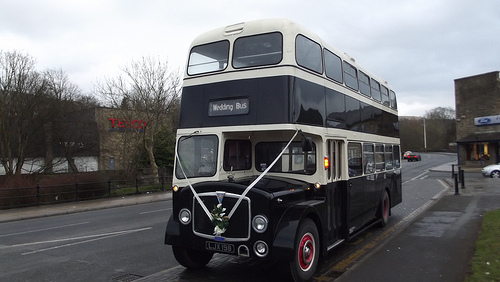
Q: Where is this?
A: This is at the road.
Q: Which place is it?
A: It is a road.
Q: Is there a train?
A: No, there are no trains.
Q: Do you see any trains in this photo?
A: No, there are no trains.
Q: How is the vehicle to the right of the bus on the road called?
A: The vehicle is a car.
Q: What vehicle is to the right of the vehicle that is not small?
A: The vehicle is a car.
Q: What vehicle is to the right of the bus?
A: The vehicle is a car.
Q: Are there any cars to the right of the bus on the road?
A: Yes, there is a car to the right of the bus.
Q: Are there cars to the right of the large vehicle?
A: Yes, there is a car to the right of the bus.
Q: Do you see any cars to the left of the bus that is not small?
A: No, the car is to the right of the bus.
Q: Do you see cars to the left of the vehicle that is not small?
A: No, the car is to the right of the bus.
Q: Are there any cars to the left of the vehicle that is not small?
A: No, the car is to the right of the bus.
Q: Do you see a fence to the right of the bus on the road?
A: No, there is a car to the right of the bus.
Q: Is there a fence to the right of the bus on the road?
A: No, there is a car to the right of the bus.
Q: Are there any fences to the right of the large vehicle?
A: No, there is a car to the right of the bus.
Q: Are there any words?
A: Yes, there are words.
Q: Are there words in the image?
A: Yes, there are words.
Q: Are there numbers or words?
A: Yes, there are words.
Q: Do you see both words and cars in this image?
A: Yes, there are both words and a car.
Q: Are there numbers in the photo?
A: No, there are no numbers.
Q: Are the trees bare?
A: Yes, the trees are bare.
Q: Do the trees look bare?
A: Yes, the trees are bare.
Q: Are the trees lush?
A: No, the trees are bare.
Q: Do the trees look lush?
A: No, the trees are bare.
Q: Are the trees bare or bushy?
A: The trees are bare.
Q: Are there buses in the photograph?
A: Yes, there is a bus.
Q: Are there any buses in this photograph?
A: Yes, there is a bus.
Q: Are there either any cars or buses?
A: Yes, there is a bus.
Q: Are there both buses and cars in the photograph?
A: Yes, there are both a bus and a car.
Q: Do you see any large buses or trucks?
A: Yes, there is a large bus.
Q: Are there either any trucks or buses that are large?
A: Yes, the bus is large.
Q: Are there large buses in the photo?
A: Yes, there is a large bus.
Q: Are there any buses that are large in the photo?
A: Yes, there is a large bus.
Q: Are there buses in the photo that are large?
A: Yes, there is a bus that is large.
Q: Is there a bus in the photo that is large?
A: Yes, there is a bus that is large.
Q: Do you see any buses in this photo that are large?
A: Yes, there is a bus that is large.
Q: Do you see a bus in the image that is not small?
A: Yes, there is a large bus.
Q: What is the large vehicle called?
A: The vehicle is a bus.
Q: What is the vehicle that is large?
A: The vehicle is a bus.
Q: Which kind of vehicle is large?
A: The vehicle is a bus.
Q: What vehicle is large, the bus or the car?
A: The bus is large.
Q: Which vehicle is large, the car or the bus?
A: The bus is large.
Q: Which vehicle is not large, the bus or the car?
A: The car is not large.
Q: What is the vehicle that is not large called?
A: The vehicle is a car.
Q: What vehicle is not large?
A: The vehicle is a car.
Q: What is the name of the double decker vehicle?
A: The vehicle is a bus.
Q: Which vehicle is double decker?
A: The vehicle is a bus.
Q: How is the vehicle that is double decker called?
A: The vehicle is a bus.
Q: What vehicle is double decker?
A: The vehicle is a bus.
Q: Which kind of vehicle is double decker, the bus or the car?
A: The bus is double decker.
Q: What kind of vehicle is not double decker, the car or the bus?
A: The car is not double decker.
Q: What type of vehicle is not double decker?
A: The vehicle is a car.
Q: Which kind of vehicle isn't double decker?
A: The vehicle is a car.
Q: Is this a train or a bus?
A: This is a bus.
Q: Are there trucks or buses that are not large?
A: No, there is a bus but it is large.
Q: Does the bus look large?
A: Yes, the bus is large.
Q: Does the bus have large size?
A: Yes, the bus is large.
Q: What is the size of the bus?
A: The bus is large.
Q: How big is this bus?
A: The bus is large.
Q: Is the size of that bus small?
A: No, the bus is large.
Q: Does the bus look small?
A: No, the bus is large.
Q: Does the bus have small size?
A: No, the bus is large.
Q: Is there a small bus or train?
A: No, there is a bus but it is large.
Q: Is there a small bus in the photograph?
A: No, there is a bus but it is large.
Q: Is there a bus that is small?
A: No, there is a bus but it is large.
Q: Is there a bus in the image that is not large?
A: No, there is a bus but it is large.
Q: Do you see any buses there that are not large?
A: No, there is a bus but it is large.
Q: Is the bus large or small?
A: The bus is large.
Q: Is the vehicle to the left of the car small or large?
A: The bus is large.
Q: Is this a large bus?
A: Yes, this is a large bus.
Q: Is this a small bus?
A: No, this is a large bus.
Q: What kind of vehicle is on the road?
A: The vehicle is a bus.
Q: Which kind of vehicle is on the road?
A: The vehicle is a bus.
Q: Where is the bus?
A: The bus is on the road.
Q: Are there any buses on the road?
A: Yes, there is a bus on the road.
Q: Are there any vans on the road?
A: No, there is a bus on the road.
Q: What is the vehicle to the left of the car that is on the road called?
A: The vehicle is a bus.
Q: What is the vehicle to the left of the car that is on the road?
A: The vehicle is a bus.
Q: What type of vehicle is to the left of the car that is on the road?
A: The vehicle is a bus.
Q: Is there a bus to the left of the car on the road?
A: Yes, there is a bus to the left of the car.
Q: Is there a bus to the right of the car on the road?
A: No, the bus is to the left of the car.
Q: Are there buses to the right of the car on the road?
A: No, the bus is to the left of the car.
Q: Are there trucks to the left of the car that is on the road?
A: No, there is a bus to the left of the car.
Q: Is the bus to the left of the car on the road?
A: Yes, the bus is to the left of the car.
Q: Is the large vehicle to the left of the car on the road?
A: Yes, the bus is to the left of the car.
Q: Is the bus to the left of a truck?
A: No, the bus is to the left of the car.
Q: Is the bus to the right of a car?
A: No, the bus is to the left of a car.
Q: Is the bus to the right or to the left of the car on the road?
A: The bus is to the left of the car.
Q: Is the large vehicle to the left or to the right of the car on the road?
A: The bus is to the left of the car.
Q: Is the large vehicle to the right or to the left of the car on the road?
A: The bus is to the left of the car.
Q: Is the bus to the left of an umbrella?
A: No, the bus is to the left of the car.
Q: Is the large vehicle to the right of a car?
A: No, the bus is to the left of a car.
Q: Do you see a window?
A: Yes, there is a window.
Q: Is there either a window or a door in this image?
A: Yes, there is a window.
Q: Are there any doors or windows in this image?
A: Yes, there is a window.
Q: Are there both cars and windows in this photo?
A: Yes, there are both a window and a car.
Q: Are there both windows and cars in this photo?
A: Yes, there are both a window and a car.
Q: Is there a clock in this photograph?
A: No, there are no clocks.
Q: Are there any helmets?
A: No, there are no helmets.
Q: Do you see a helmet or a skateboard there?
A: No, there are no helmets or skateboards.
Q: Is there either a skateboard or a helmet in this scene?
A: No, there are no helmets or skateboards.